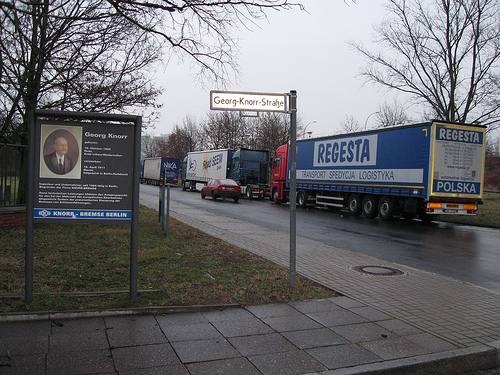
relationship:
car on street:
[201, 177, 240, 202] [140, 184, 499, 290]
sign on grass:
[211, 90, 297, 286] [0, 202, 342, 320]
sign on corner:
[211, 90, 297, 286] [294, 233, 499, 372]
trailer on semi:
[287, 119, 487, 200] [270, 145, 433, 222]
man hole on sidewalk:
[350, 263, 405, 277] [140, 193, 500, 374]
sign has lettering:
[211, 90, 297, 286] [213, 97, 284, 108]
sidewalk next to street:
[140, 193, 500, 374] [140, 184, 499, 290]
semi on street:
[270, 145, 433, 222] [140, 184, 499, 290]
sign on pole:
[26, 108, 139, 220] [130, 221, 139, 305]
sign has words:
[26, 108, 139, 220] [39, 125, 131, 205]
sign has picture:
[26, 108, 139, 220] [39, 123, 83, 179]